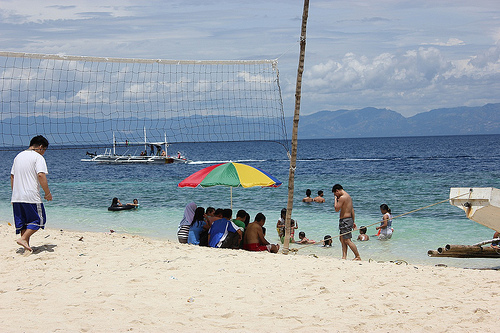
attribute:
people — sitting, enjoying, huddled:
[175, 202, 275, 251]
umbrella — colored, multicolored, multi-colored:
[180, 158, 283, 195]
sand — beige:
[3, 225, 499, 332]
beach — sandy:
[1, 185, 496, 329]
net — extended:
[1, 49, 291, 165]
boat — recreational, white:
[86, 126, 183, 169]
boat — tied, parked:
[441, 174, 498, 235]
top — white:
[8, 148, 47, 208]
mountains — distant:
[1, 100, 498, 145]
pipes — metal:
[426, 241, 499, 261]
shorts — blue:
[10, 197, 48, 231]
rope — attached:
[289, 193, 466, 254]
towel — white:
[184, 202, 198, 222]